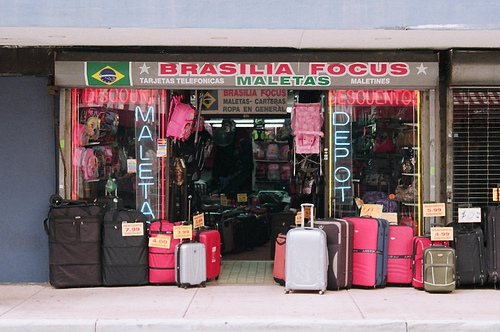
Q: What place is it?
A: It is a store.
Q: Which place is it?
A: It is a store.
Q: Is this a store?
A: Yes, it is a store.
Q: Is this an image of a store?
A: Yes, it is showing a store.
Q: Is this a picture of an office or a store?
A: It is showing a store.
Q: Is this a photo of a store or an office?
A: It is showing a store.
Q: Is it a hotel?
A: No, it is a store.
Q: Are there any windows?
A: Yes, there is a window.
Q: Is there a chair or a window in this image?
A: Yes, there is a window.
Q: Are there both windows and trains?
A: No, there is a window but no trains.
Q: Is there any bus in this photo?
A: No, there are no buses.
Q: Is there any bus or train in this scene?
A: No, there are no buses or trains.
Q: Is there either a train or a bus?
A: No, there are no buses or trains.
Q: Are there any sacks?
A: No, there are no sacks.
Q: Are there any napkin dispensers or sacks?
A: No, there are no sacks or napkin dispensers.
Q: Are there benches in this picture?
A: No, there are no benches.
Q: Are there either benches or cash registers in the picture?
A: No, there are no benches or cash registers.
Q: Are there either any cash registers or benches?
A: No, there are no benches or cash registers.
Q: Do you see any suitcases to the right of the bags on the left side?
A: Yes, there is a suitcase to the right of the bags.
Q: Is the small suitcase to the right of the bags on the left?
A: Yes, the suitcase is to the right of the bags.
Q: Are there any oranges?
A: No, there are no oranges.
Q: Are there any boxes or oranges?
A: No, there are no oranges or boxes.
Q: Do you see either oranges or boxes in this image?
A: No, there are no oranges or boxes.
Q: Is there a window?
A: Yes, there is a window.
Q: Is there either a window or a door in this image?
A: Yes, there is a window.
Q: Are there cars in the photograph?
A: No, there are no cars.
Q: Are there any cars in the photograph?
A: No, there are no cars.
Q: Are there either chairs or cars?
A: No, there are no cars or chairs.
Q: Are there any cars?
A: No, there are no cars.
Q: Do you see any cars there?
A: No, there are no cars.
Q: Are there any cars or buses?
A: No, there are no cars or buses.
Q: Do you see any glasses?
A: No, there are no glasses.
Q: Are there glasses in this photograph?
A: No, there are no glasses.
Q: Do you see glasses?
A: No, there are no glasses.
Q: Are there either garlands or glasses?
A: No, there are no glasses or garlands.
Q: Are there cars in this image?
A: No, there are no cars.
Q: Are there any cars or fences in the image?
A: No, there are no cars or fences.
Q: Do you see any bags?
A: Yes, there is a bag.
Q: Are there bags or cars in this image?
A: Yes, there is a bag.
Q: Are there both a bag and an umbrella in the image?
A: No, there is a bag but no umbrellas.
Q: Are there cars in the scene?
A: No, there are no cars.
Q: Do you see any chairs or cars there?
A: No, there are no cars or chairs.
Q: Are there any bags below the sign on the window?
A: Yes, there is a bag below the sign.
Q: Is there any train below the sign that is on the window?
A: No, there is a bag below the sign.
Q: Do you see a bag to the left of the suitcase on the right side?
A: Yes, there is a bag to the left of the suitcase.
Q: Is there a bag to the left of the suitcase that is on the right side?
A: Yes, there is a bag to the left of the suitcase.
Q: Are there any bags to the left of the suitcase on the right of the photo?
A: Yes, there is a bag to the left of the suitcase.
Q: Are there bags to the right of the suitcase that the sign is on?
A: No, the bag is to the left of the suitcase.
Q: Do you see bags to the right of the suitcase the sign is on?
A: No, the bag is to the left of the suitcase.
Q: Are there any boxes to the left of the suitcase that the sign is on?
A: No, there is a bag to the left of the suitcase.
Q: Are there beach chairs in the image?
A: No, there are no beach chairs.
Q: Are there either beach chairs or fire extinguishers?
A: No, there are no beach chairs or fire extinguishers.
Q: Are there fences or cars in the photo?
A: No, there are no cars or fences.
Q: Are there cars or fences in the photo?
A: No, there are no cars or fences.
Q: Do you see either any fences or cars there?
A: No, there are no cars or fences.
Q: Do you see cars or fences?
A: No, there are no cars or fences.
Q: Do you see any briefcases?
A: No, there are no briefcases.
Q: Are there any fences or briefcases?
A: No, there are no briefcases or fences.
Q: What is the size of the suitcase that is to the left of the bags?
A: The suitcase is large.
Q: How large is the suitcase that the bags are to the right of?
A: The suitcase is large.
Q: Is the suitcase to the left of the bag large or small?
A: The suitcase is large.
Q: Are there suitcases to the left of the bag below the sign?
A: Yes, there is a suitcase to the left of the bag.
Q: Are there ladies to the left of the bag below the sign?
A: No, there is a suitcase to the left of the bag.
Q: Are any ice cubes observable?
A: No, there are no ice cubes.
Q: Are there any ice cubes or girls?
A: No, there are no ice cubes or girls.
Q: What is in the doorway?
A: The stroller is in the doorway.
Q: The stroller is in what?
A: The stroller is in the doorway.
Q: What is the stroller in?
A: The stroller is in the doorway.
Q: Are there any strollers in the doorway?
A: Yes, there is a stroller in the doorway.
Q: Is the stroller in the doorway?
A: Yes, the stroller is in the doorway.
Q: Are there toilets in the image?
A: No, there are no toilets.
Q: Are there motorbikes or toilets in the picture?
A: No, there are no toilets or motorbikes.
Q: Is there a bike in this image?
A: No, there are no bikes.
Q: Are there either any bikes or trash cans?
A: No, there are no bikes or trash cans.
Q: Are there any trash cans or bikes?
A: No, there are no bikes or trash cans.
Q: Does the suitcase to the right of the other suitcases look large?
A: Yes, the suitcase is large.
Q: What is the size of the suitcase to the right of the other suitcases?
A: The suitcase is large.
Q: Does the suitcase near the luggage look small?
A: No, the suitcase is large.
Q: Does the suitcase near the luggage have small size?
A: No, the suitcase is large.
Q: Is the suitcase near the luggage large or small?
A: The suitcase is large.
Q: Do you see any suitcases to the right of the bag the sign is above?
A: Yes, there is a suitcase to the right of the bag.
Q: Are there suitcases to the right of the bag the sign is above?
A: Yes, there is a suitcase to the right of the bag.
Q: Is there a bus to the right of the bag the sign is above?
A: No, there is a suitcase to the right of the bag.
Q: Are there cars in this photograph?
A: No, there are no cars.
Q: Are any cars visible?
A: No, there are no cars.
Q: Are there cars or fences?
A: No, there are no cars or fences.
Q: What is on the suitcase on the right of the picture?
A: The sign is on the suitcase.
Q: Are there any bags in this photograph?
A: Yes, there is a bag.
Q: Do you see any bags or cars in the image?
A: Yes, there is a bag.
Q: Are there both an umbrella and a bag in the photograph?
A: No, there is a bag but no umbrellas.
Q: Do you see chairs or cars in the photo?
A: No, there are no cars or chairs.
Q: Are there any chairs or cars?
A: No, there are no cars or chairs.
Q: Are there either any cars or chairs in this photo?
A: No, there are no cars or chairs.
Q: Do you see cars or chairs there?
A: No, there are no cars or chairs.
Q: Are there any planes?
A: No, there are no planes.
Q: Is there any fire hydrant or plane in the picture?
A: No, there are no airplanes or fire hydrants.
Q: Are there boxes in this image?
A: No, there are no boxes.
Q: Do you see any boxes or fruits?
A: No, there are no boxes or fruits.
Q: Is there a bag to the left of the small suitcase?
A: Yes, there are bags to the left of the suitcase.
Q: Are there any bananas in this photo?
A: No, there are no bananas.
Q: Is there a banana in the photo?
A: No, there are no bananas.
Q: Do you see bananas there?
A: No, there are no bananas.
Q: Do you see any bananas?
A: No, there are no bananas.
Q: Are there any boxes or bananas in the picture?
A: No, there are no bananas or boxes.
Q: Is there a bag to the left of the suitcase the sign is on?
A: Yes, there are bags to the left of the suitcase.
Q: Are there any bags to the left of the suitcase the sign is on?
A: Yes, there are bags to the left of the suitcase.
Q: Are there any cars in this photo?
A: No, there are no cars.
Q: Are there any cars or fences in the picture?
A: No, there are no cars or fences.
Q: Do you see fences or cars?
A: No, there are no cars or fences.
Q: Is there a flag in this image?
A: Yes, there is a flag.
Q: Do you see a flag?
A: Yes, there is a flag.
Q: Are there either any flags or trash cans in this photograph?
A: Yes, there is a flag.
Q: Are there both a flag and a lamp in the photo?
A: No, there is a flag but no lamps.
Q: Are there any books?
A: No, there are no books.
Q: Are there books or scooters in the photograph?
A: No, there are no books or scooters.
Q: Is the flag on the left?
A: Yes, the flag is on the left of the image.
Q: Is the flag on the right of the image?
A: No, the flag is on the left of the image.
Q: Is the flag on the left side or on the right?
A: The flag is on the left of the image.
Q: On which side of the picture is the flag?
A: The flag is on the left of the image.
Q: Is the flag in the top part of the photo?
A: Yes, the flag is in the top of the image.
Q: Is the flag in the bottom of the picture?
A: No, the flag is in the top of the image.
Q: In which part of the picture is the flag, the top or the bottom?
A: The flag is in the top of the image.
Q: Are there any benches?
A: No, there are no benches.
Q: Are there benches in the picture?
A: No, there are no benches.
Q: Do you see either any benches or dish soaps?
A: No, there are no benches or dish soaps.